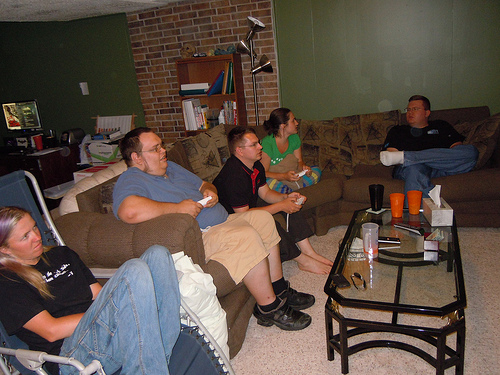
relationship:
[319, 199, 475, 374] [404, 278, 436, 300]
table topped with glass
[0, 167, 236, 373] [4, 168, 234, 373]
chair framed with fabric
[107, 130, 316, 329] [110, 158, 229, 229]
man wearing shirt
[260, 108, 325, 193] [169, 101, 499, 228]
girl sitting on couch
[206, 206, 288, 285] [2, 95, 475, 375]
shorts on people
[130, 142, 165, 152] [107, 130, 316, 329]
eyeglasses on man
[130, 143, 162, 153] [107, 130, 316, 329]
eyeglasses on man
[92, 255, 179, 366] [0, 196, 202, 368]
jeans on woman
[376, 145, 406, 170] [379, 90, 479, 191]
sock on man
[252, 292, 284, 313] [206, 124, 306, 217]
sock on man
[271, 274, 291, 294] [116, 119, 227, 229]
sock on man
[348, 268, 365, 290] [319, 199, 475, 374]
sunglasses on table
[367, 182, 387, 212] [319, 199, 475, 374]
black cup on table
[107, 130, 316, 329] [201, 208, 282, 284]
man wearing shorts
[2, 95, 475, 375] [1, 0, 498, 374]
people sitting in living room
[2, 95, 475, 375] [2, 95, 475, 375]
people sitting in people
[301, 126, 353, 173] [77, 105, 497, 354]
pillow on couch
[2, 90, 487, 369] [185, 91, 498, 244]
people on couch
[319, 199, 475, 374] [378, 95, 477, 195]
table in front of person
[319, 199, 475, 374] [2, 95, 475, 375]
table in front of people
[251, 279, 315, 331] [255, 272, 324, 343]
shoes on feet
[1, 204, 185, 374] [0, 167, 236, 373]
woman in chair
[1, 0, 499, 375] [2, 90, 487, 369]
living room of people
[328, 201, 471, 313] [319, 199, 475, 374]
surface on table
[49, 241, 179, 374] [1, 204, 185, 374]
jeans on woman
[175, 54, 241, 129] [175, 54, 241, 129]
books/shelf on books/shelf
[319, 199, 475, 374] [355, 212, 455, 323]
table with glass